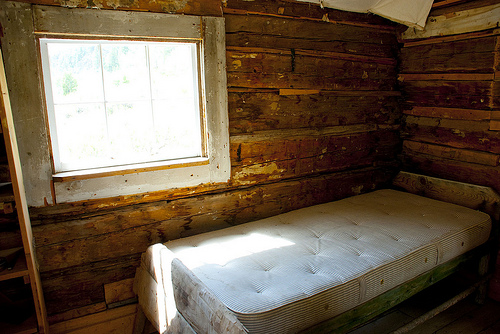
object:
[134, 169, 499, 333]
bed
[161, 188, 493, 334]
mattress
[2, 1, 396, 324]
wall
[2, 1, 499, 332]
cabin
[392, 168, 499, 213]
headboard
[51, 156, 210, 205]
sill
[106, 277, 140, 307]
board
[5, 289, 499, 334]
floor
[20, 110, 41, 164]
paint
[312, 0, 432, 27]
insulation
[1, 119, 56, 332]
shelf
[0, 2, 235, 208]
trim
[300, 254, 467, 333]
box spring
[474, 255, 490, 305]
pole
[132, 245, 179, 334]
cloth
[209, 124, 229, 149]
wood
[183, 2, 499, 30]
ceiling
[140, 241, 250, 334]
footboard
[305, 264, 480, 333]
board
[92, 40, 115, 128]
tree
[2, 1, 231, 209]
frame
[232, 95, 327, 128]
logs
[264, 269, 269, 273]
buttons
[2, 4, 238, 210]
window